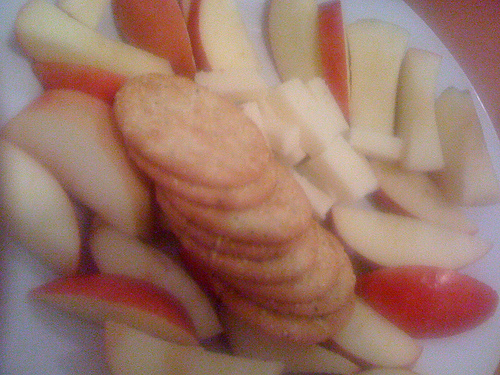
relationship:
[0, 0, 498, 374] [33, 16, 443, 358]
food in background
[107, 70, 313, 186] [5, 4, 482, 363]
cracker on plate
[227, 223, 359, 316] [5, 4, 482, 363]
cracker on plate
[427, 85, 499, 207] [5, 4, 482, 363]
apple slice on plate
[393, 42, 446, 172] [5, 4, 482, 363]
apple slice on plate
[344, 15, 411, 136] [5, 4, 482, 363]
apple slice on plate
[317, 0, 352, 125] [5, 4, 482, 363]
apple slice on plate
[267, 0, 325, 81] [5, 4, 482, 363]
apple slice on plate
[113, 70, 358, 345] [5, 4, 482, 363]
crackers on plate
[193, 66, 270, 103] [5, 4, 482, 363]
cheese on plate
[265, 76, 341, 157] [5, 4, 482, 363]
cheese on plate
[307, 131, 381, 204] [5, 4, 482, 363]
cheese on plate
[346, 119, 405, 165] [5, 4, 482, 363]
cheese on plate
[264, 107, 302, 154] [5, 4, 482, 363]
cheese on plate